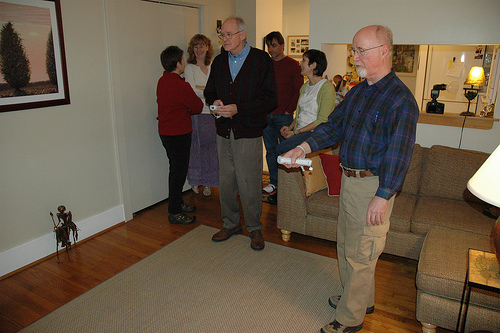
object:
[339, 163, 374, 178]
belt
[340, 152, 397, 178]
waist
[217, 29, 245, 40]
glasses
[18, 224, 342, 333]
carpet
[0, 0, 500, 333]
room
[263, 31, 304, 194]
man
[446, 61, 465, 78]
paper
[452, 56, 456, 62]
magnet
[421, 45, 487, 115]
fridge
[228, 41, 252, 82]
shirt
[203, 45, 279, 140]
sweater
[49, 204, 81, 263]
figurine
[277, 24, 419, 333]
man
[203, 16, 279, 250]
man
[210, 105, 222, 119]
remote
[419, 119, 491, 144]
ground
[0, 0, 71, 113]
painting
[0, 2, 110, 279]
wall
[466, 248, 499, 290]
table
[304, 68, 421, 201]
blue shirt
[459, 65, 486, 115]
lamp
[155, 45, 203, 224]
people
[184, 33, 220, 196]
people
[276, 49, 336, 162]
people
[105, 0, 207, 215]
door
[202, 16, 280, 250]
people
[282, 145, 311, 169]
hand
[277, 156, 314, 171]
controller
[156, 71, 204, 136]
shirt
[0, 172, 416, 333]
floor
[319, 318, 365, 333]
shoes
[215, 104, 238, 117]
hand